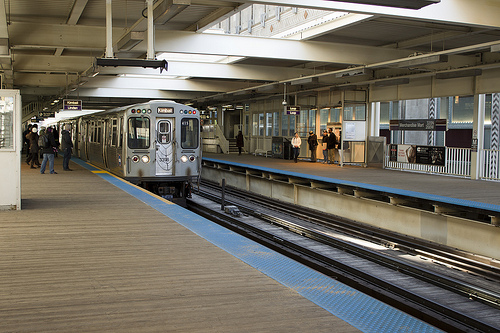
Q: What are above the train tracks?
A: Metal Rafters.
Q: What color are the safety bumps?
A: Blue.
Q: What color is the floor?
A: Brown.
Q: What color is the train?
A: Grey.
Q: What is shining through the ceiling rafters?
A: Sunlight.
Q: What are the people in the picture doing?
A: Waiting on the train.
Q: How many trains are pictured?
A: One.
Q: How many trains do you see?
A: 1.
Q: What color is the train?
A: Gray.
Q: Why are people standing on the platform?
A: They are waiting for the train.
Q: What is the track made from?
A: Metal.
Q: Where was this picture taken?
A: A train station.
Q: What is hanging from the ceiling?
A: Lights and signs.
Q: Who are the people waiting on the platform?
A: Passengers.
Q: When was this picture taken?
A: During the day.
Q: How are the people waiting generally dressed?
A: Cold weather clothes.